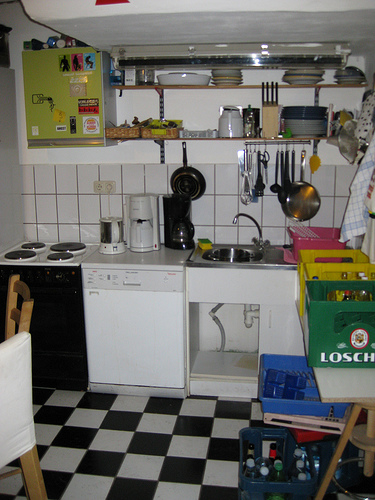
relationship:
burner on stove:
[47, 252, 74, 261] [1, 241, 101, 392]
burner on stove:
[4, 250, 36, 260] [1, 241, 101, 392]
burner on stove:
[21, 242, 44, 250] [1, 241, 101, 392]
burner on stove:
[51, 243, 85, 251] [1, 241, 101, 392]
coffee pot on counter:
[124, 193, 159, 251] [81, 244, 194, 271]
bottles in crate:
[243, 441, 310, 480] [237, 426, 317, 498]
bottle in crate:
[268, 443, 278, 458] [237, 426, 317, 498]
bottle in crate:
[246, 444, 256, 460] [237, 426, 317, 498]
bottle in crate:
[289, 451, 303, 473] [237, 426, 317, 498]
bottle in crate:
[243, 458, 257, 479] [237, 426, 317, 498]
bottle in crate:
[256, 456, 272, 477] [237, 426, 317, 498]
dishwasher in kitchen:
[81, 244, 195, 399] [0, 1, 373, 500]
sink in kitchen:
[202, 246, 264, 262] [0, 1, 373, 500]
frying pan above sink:
[170, 141, 206, 200] [202, 246, 264, 262]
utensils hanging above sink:
[241, 141, 294, 205] [202, 246, 264, 262]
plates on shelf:
[280, 105, 327, 136] [109, 136, 335, 141]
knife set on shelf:
[260, 81, 280, 138] [109, 136, 335, 141]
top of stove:
[1, 241, 99, 267] [1, 241, 101, 392]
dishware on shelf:
[111, 62, 367, 83] [109, 82, 368, 89]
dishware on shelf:
[106, 82, 357, 135] [109, 136, 335, 141]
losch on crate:
[319, 352, 374, 364] [303, 280, 374, 368]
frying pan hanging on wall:
[170, 141, 206, 200] [1, 1, 366, 247]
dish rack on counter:
[286, 227, 349, 261] [260, 245, 356, 270]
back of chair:
[0, 331, 35, 470] [0, 332, 48, 500]